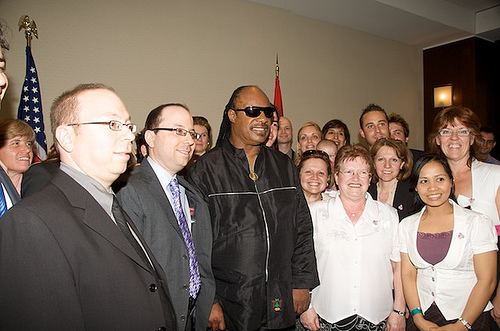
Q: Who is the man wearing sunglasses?
A: Stevie Wonder.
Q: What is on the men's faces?
A: Glasses.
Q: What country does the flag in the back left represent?
A: United States.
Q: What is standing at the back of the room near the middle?
A: Flag.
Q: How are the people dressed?
A: Business casual.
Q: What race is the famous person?
A: African American.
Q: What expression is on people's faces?
A: They are smiling.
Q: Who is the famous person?
A: Stevie Wonder.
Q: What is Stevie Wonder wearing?
A: A jacket.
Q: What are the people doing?
A: Taking a picture with Stevie Wonder.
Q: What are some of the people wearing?
A: Glasses.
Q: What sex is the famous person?
A: Male.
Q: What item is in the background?
A: The American flag.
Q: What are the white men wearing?
A: Suits.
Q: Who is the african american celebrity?
A: Stevie Wonder.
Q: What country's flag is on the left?
A: United States.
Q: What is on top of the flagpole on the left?
A: Eagle.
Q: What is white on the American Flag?
A: Stars.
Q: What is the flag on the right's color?
A: Red.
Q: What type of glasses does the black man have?
A: Sunglasses.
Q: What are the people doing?
A: Posing for picture.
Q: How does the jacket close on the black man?
A: Zipper.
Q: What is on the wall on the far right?
A: Light.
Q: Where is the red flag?
A: Behind black man.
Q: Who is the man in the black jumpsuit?
A: Stevie Wonder.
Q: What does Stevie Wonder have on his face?
A: Glasses.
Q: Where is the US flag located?
A: On left.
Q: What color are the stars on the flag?
A: White.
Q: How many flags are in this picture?
A: 2.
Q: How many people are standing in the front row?
A: 5.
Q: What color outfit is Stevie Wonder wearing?
A: Black.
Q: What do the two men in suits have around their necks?
A: Ties.